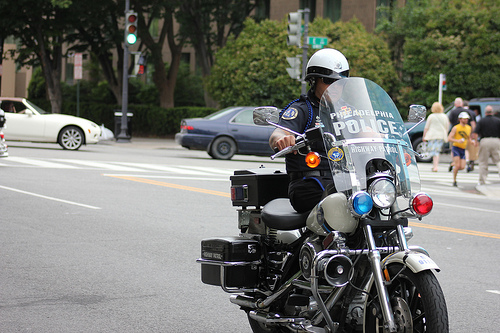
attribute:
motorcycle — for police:
[184, 75, 451, 331]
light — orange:
[304, 153, 322, 170]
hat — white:
[461, 113, 467, 119]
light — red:
[410, 191, 437, 213]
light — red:
[350, 191, 371, 213]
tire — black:
[212, 135, 234, 158]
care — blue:
[177, 85, 299, 177]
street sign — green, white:
[306, 34, 331, 49]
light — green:
[125, 31, 145, 47]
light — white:
[370, 177, 399, 211]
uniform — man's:
[286, 100, 316, 193]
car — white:
[0, 92, 114, 151]